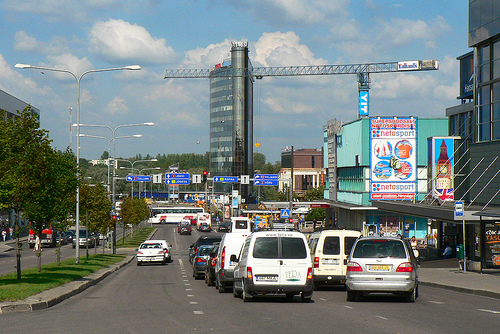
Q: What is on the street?
A: Vehicles.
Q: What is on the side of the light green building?
A: An advertisement.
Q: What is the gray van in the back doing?
A: Switching lanes.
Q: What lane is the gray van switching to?
A: The furthest right lane.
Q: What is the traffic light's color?
A: Red.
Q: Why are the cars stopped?
A: The light is red.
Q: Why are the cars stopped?
A: Stop light.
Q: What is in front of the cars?
A: A stop light.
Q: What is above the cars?
A: A metal structure.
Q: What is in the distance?
A: A building.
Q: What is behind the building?
A: Trees.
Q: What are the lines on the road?
A: Lane markers.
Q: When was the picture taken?
A: Daytime.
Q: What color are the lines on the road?
A: White.